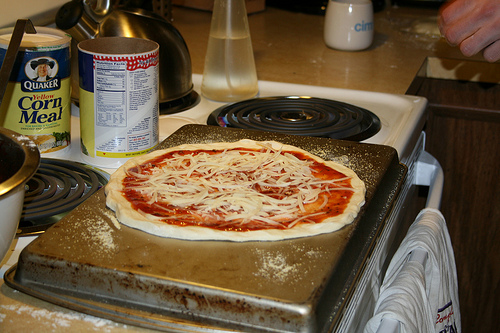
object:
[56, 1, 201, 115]
kettle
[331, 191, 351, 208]
sauce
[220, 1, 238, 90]
straw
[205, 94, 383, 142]
burner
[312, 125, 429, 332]
oven door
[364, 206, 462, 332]
towel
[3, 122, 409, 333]
pan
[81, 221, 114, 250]
flour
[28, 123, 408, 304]
surface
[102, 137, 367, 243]
cheese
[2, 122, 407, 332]
baking pan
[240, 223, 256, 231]
tomato sauce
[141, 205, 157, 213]
sauce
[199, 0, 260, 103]
bottle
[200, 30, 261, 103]
liquid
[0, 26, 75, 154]
container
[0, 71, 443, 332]
oven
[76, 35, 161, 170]
container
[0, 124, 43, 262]
bowl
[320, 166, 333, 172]
sauce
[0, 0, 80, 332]
left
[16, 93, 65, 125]
corn-meal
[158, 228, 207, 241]
crust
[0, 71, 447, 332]
stove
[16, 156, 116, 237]
burner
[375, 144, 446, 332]
handle